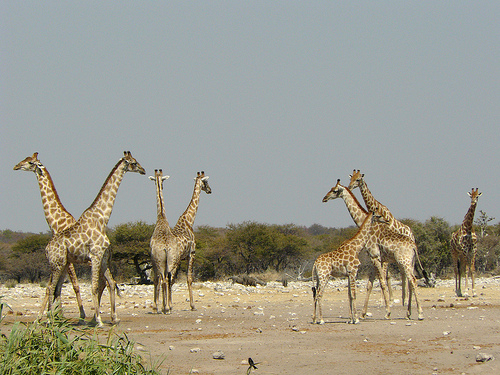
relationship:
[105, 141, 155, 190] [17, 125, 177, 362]
head of giraffe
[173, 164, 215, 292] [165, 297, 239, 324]
giraffe on ground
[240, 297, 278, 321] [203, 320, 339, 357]
rocks on ground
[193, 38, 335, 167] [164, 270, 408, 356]
sky above land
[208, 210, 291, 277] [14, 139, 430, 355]
trees behind giraffes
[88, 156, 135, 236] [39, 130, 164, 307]
neck of giraffe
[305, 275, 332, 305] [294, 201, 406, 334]
tail of giraffe